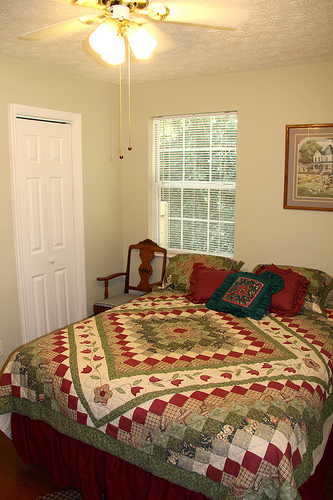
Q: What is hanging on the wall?
A: Painting.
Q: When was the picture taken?
A: Daytime.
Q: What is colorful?
A: Bedspread.